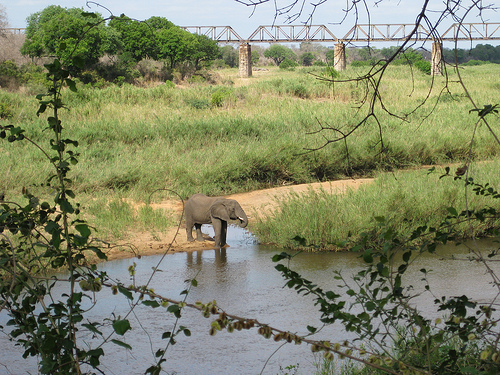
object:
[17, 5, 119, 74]
tree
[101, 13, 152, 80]
tree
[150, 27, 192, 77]
tree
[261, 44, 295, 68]
tree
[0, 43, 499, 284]
ground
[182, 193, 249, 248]
fur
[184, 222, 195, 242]
leg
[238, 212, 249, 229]
trunk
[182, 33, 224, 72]
tree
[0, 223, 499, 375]
water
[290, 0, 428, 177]
tree branches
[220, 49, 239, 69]
trees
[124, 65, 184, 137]
wall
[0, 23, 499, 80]
bridge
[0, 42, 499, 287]
grass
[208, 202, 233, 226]
ear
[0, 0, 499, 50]
sky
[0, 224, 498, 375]
ripples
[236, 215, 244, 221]
tusk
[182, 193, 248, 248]
elephant